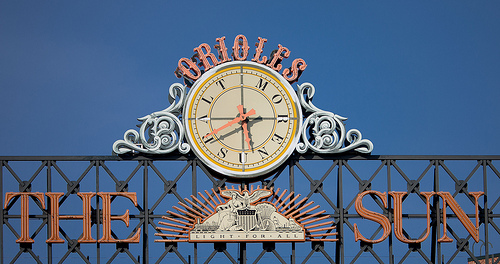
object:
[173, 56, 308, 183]
clock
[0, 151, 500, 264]
fence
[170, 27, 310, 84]
orioles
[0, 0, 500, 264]
baltimore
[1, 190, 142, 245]
word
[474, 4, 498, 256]
right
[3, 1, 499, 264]
light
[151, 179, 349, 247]
logo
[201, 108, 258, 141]
hands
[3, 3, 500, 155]
sky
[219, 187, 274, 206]
eagle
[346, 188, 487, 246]
words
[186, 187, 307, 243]
sign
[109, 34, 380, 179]
sign